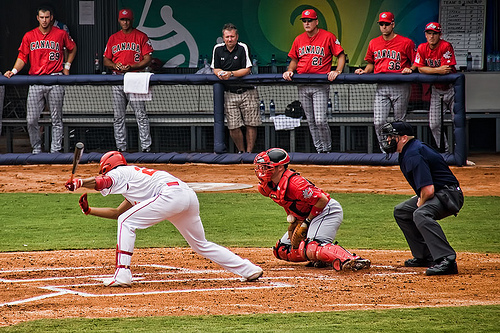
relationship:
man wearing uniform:
[65, 149, 262, 286] [285, 28, 345, 152]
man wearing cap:
[65, 149, 262, 286] [422, 21, 442, 32]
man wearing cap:
[65, 149, 262, 286] [375, 10, 395, 22]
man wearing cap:
[414, 20, 457, 155] [375, 10, 395, 22]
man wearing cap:
[414, 20, 457, 165] [375, 10, 395, 22]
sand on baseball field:
[1, 249, 497, 324] [1, 157, 499, 331]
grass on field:
[2, 180, 499, 268] [1, 167, 496, 329]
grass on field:
[0, 303, 500, 332] [1, 167, 496, 329]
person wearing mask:
[245, 141, 377, 273] [250, 142, 295, 188]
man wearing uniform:
[65, 149, 262, 286] [15, 26, 70, 148]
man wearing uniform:
[65, 149, 262, 286] [99, 27, 152, 152]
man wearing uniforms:
[65, 149, 262, 286] [16, 8, 462, 132]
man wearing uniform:
[65, 149, 262, 286] [91, 164, 263, 287]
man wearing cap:
[65, 142, 267, 299] [114, 7, 136, 28]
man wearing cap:
[414, 20, 457, 155] [296, 5, 321, 23]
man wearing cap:
[414, 20, 457, 155] [417, 17, 444, 34]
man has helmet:
[65, 149, 262, 286] [83, 147, 125, 167]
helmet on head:
[83, 147, 125, 167] [98, 150, 127, 176]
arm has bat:
[65, 176, 112, 192] [66, 142, 87, 188]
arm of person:
[80, 187, 127, 227] [103, 159, 253, 293]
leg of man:
[103, 192, 187, 286] [65, 149, 262, 286]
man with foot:
[65, 149, 262, 286] [100, 277, 122, 286]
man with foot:
[65, 149, 262, 286] [248, 270, 263, 280]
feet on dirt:
[238, 265, 268, 283] [51, 263, 345, 303]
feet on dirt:
[100, 273, 131, 286] [51, 263, 345, 303]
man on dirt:
[65, 149, 262, 286] [51, 263, 345, 303]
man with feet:
[65, 149, 262, 286] [238, 265, 268, 283]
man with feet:
[65, 149, 262, 286] [100, 273, 131, 286]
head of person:
[243, 145, 299, 197] [245, 141, 377, 273]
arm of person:
[92, 198, 134, 218] [245, 141, 377, 273]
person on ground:
[253, 147, 371, 270] [280, 260, 431, 300]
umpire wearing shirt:
[376, 121, 466, 276] [396, 143, 435, 191]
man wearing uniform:
[65, 149, 262, 286] [72, 164, 277, 282]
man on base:
[65, 149, 262, 286] [60, 257, 210, 296]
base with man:
[60, 257, 210, 296] [65, 149, 262, 286]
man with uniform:
[65, 149, 262, 286] [10, 34, 70, 146]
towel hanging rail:
[118, 66, 159, 109] [29, 75, 439, 93]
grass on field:
[0, 191, 500, 256] [1, 167, 496, 329]